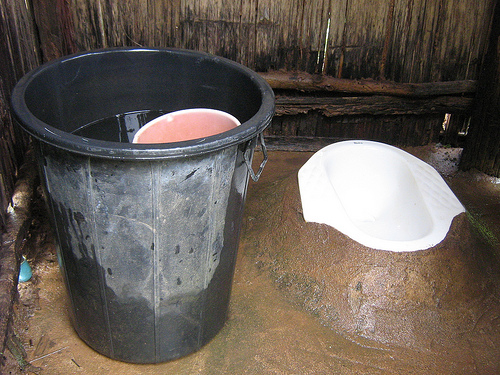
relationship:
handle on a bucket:
[241, 141, 273, 183] [12, 50, 289, 370]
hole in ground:
[289, 134, 464, 251] [254, 149, 499, 372]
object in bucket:
[130, 105, 231, 149] [19, 58, 238, 363]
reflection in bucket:
[112, 100, 142, 140] [55, 49, 270, 339]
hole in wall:
[434, 110, 454, 139] [220, 2, 487, 142]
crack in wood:
[318, 13, 333, 75] [45, 4, 492, 142]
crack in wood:
[440, 113, 456, 143] [45, 4, 492, 142]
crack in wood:
[454, 110, 472, 140] [45, 4, 492, 142]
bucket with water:
[26, 36, 280, 369] [65, 91, 252, 156]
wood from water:
[254, 0, 476, 152] [92, 124, 130, 137]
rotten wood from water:
[3, 2, 498, 143] [65, 103, 246, 157]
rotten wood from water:
[0, 2, 29, 374] [65, 103, 246, 157]